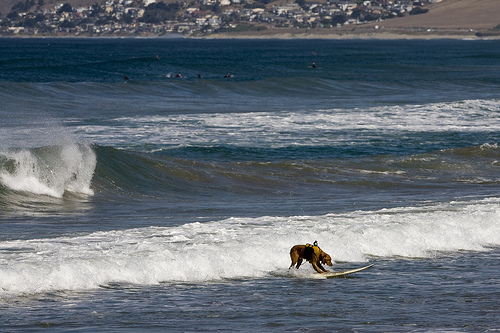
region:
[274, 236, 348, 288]
brown dog on surf board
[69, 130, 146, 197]
white and blue ocean waves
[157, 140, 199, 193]
white and blue ocean waves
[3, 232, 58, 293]
white and blue ocean waves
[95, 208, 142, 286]
white and blue ocean waves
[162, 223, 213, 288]
white and blue ocean waves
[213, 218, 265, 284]
white and blue ocean waves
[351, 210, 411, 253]
white and blue ocean waves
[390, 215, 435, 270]
white and blue ocean waves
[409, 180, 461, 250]
white and blue ocean waves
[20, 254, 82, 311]
Ripples in the water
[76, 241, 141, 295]
Ripples in the water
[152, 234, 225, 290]
Ripples in the water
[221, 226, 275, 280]
Ripples in the water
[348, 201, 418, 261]
Ripples in the water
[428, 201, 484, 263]
Ripples in the water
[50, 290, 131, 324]
Ripples in the water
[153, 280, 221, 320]
Ripples in the water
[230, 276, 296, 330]
Ripples in the water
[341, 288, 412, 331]
Ripples in the water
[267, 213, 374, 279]
dog on a surfboard in the water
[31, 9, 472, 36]
city off in the distance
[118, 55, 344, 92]
surfers off in the water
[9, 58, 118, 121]
turquoise blue ocean water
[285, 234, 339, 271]
puppy surfing on a wave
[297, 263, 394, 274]
white surfboard of a puppy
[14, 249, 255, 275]
white foam on the ocean wave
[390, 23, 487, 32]
road off in the distance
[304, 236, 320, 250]
harness on the puppys back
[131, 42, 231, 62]
surfer riding in on a wave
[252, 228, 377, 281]
dog in the ocean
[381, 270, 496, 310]
water is calm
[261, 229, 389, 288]
dog catching a wave with his board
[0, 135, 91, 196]
small wave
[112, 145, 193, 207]
outside of a wave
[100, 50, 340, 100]
people swiming in the distance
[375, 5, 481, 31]
land in the distance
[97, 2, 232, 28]
rocks across the water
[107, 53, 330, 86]
people in the background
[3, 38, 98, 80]
mini waves forming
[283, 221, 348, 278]
dog on surfboard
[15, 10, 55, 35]
white clouds in blue sky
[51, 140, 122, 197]
white and blue ocean waves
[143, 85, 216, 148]
white and blue ocean waves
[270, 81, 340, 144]
white and blue ocean waves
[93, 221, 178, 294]
white and blue ocean waves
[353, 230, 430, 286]
white and blue ocean waves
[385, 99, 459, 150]
white and blue ocean waves